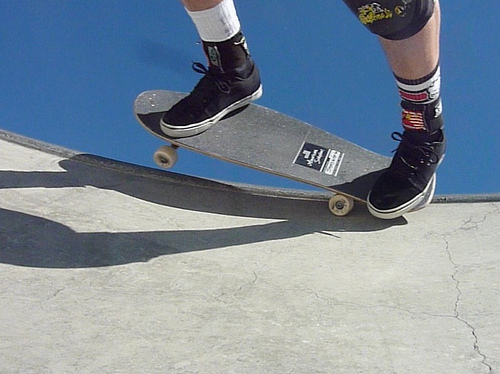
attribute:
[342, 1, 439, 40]
knee pad — black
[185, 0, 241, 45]
sock — white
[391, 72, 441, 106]
socks — white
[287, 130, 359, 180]
sticker — black, white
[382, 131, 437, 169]
laces — black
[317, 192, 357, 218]
wheel — white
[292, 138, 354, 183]
sticker — Black , white 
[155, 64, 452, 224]
shoes — black 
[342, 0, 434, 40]
kneepad — black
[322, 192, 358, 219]
white wheel — white 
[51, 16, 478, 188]
sky — dark, blue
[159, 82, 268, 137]
sole — white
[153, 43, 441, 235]
shoe — black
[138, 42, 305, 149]
shoe — black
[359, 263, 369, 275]
patch — black , asphalt 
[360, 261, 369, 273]
asphalt — black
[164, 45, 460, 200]
sneakers — black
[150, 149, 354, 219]
wheels —  white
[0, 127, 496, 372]
concrete — gray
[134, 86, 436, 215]
skateboard —  black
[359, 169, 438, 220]
sole — white